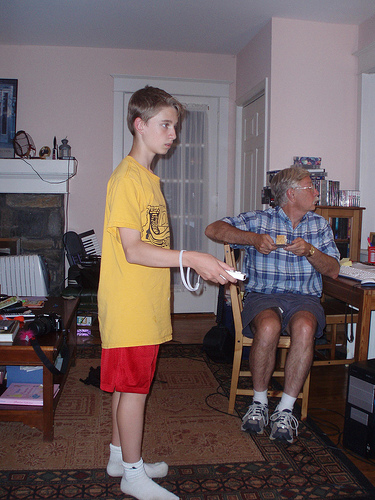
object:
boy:
[96, 84, 238, 500]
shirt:
[96, 155, 174, 350]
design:
[140, 204, 171, 250]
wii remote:
[219, 269, 247, 282]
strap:
[178, 248, 200, 292]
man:
[204, 162, 341, 445]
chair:
[223, 242, 311, 421]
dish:
[271, 242, 295, 249]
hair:
[270, 162, 310, 208]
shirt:
[219, 207, 341, 298]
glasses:
[296, 183, 314, 195]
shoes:
[241, 401, 270, 437]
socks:
[252, 388, 269, 407]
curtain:
[150, 101, 210, 293]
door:
[110, 70, 234, 317]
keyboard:
[79, 228, 103, 259]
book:
[0, 382, 61, 408]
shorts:
[99, 343, 160, 395]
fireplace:
[0, 192, 66, 297]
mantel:
[0, 156, 79, 196]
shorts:
[240, 290, 326, 342]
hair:
[126, 82, 188, 137]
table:
[321, 260, 375, 363]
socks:
[118, 456, 179, 500]